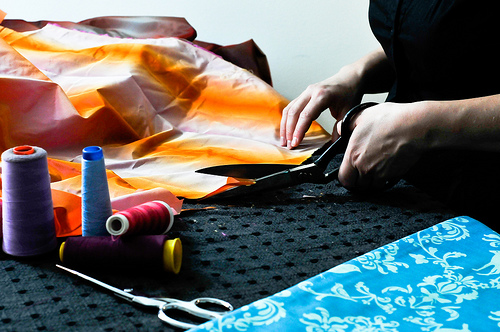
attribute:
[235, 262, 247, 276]
hole — black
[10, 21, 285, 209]
fabric — white, orange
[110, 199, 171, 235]
thread — red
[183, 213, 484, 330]
fabric — blue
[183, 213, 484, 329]
pattern — white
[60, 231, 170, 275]
thread — dark colored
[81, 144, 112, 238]
spool — blue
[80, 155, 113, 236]
thread — white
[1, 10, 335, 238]
fabric — orange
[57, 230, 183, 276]
spool — yellow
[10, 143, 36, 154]
spool — orange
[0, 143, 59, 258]
thread — white, purple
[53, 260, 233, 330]
scissors — Silver 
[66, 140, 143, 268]
blue thread — blue 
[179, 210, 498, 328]
blue cloth — blue 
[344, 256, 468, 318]
white design — with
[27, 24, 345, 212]
fabric — orange , white  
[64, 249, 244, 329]
scissors — silver 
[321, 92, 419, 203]
black handle — black 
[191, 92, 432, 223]
scissors — Large 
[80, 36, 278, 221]
material — Orange , white 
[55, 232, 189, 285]
spool — Purple 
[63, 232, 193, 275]
thread — Purple 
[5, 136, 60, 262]
spool — Lavender  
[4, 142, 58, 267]
thread — Lavender  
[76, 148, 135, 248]
spool — Blue   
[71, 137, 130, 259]
thread — Blue   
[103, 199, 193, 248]
spool — Red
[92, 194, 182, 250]
thread — Red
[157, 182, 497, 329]
material — Light blue